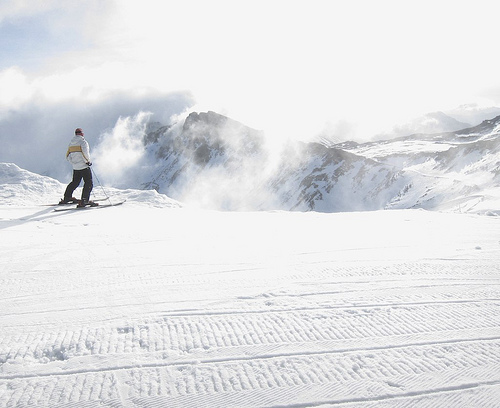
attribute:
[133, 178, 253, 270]
cliff — white, high, steep, foggy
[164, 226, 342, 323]
snow — white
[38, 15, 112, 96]
sky — blue, white